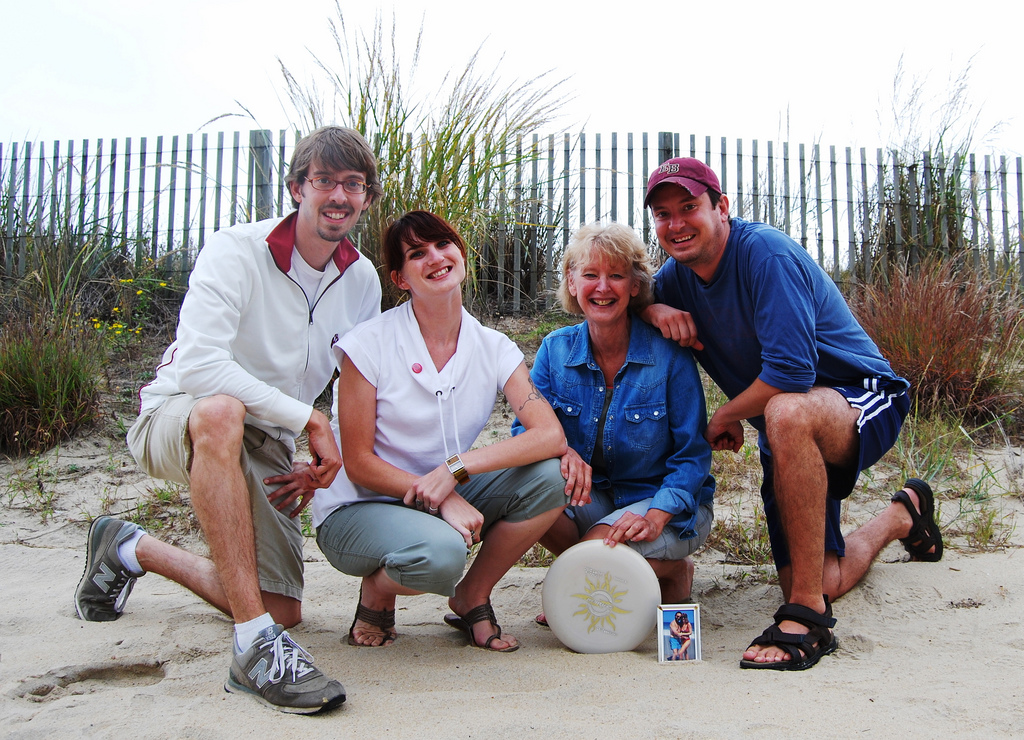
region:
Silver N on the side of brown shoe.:
[219, 631, 347, 704]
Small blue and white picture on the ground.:
[643, 563, 716, 668]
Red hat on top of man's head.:
[634, 151, 718, 191]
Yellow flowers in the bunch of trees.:
[35, 233, 184, 352]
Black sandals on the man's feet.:
[746, 572, 950, 674]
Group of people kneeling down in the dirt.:
[81, 104, 955, 694]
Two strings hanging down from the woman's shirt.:
[424, 382, 467, 472]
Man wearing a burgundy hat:
[633, 158, 957, 675]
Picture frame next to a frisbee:
[655, 598, 703, 657]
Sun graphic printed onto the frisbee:
[564, 569, 637, 640]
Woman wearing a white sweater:
[310, 202, 574, 652]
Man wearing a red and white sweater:
[71, 129, 382, 711]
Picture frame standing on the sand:
[655, 603, 704, 665]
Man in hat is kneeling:
[631, 152, 926, 669]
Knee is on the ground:
[256, 585, 307, 625]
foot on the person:
[244, 642, 328, 701]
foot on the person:
[329, 585, 387, 644]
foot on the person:
[463, 607, 522, 652]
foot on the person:
[741, 604, 846, 671]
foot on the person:
[895, 483, 960, 540]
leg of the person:
[152, 530, 226, 606]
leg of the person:
[776, 458, 843, 563]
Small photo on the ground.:
[661, 595, 704, 656]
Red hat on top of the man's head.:
[626, 162, 728, 197]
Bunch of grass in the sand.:
[939, 408, 1003, 486]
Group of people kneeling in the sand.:
[198, 119, 806, 607]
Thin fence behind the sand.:
[43, 110, 736, 279]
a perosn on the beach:
[549, 209, 687, 580]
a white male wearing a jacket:
[149, 120, 383, 481]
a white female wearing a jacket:
[326, 203, 536, 460]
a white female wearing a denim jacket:
[524, 218, 680, 472]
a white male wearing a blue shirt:
[640, 154, 888, 385]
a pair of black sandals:
[729, 473, 958, 671]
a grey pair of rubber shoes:
[44, 512, 355, 722]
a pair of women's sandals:
[340, 568, 521, 668]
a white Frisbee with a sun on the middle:
[537, 531, 667, 662]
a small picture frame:
[650, 590, 712, 671]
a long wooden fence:
[6, 132, 1022, 330]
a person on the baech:
[620, 117, 1006, 649]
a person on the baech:
[506, 260, 734, 731]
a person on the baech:
[125, 120, 429, 643]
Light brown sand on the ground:
[8, 377, 1010, 736]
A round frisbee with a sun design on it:
[538, 529, 653, 665]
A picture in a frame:
[646, 599, 711, 664]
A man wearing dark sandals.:
[611, 159, 988, 688]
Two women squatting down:
[290, 180, 755, 683]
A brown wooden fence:
[5, 136, 1017, 301]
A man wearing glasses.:
[125, 131, 386, 721]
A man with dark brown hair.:
[129, 130, 414, 690]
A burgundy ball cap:
[634, 149, 726, 203]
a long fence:
[6, 142, 1021, 330]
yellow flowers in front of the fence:
[81, 278, 149, 339]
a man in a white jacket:
[138, 145, 389, 700]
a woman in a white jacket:
[353, 222, 528, 589]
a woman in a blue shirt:
[531, 224, 712, 569]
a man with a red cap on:
[648, 161, 928, 659]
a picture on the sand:
[656, 604, 704, 666]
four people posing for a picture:
[75, 160, 932, 686]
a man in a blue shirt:
[648, 162, 912, 635]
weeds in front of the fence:
[840, 246, 1006, 525]